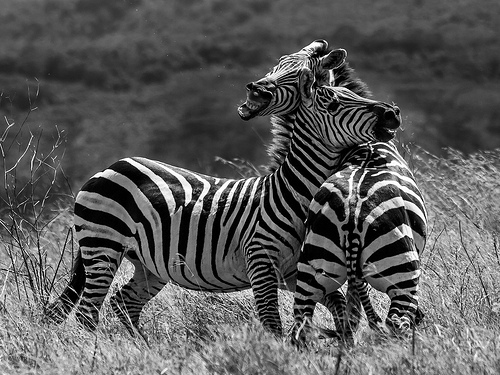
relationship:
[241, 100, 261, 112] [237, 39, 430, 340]
teeth on zebra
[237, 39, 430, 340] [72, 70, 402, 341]
zebra on zebra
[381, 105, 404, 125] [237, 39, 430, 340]
nostrils on zebra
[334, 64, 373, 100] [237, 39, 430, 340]
hair on zebra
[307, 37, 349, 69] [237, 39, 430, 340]
ears on zebra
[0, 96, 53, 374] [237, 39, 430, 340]
grass behind zebra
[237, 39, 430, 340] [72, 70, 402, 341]
zebra touching zebra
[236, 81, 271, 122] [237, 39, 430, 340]
mouth on zebra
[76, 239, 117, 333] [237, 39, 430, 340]
legs on zebra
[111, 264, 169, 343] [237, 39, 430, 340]
legs on zebra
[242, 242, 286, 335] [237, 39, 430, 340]
legs on zebra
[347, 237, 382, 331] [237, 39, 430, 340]
tail on zebra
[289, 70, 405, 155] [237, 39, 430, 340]
head on zebra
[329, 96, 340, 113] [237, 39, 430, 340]
eye on zebra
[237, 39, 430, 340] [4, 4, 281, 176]
zebra in field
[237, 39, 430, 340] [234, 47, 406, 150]
zebra nuzzle heads